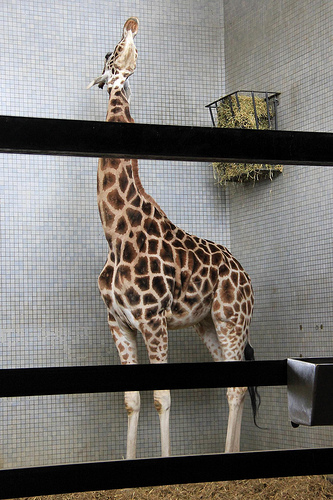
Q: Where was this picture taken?
A: Zoo.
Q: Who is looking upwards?
A: Giraffe.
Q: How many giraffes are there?
A: 1.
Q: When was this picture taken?
A: Daytime.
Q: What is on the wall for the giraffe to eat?
A: Hay.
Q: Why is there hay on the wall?
A: Giraffes food.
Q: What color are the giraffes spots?
A: Brown.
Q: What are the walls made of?
A: Tile.